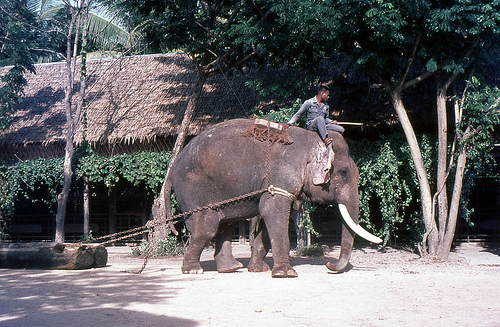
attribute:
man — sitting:
[307, 85, 338, 138]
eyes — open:
[339, 166, 351, 180]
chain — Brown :
[73, 187, 180, 262]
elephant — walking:
[166, 117, 383, 279]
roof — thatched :
[82, 62, 189, 134]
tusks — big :
[330, 180, 404, 260]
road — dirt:
[1, 255, 496, 322]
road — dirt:
[22, 180, 442, 322]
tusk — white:
[327, 203, 390, 249]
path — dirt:
[457, 224, 493, 277]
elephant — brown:
[156, 110, 387, 282]